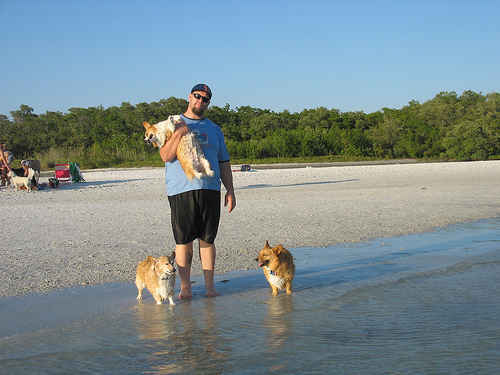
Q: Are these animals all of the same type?
A: Yes, all the animals are dogs.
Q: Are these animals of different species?
A: No, all the animals are dogs.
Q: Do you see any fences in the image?
A: No, there are no fences.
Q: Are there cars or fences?
A: No, there are no fences or cars.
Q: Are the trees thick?
A: Yes, the trees are thick.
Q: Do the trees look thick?
A: Yes, the trees are thick.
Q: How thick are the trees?
A: The trees are thick.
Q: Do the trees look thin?
A: No, the trees are thick.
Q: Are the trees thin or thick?
A: The trees are thick.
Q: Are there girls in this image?
A: No, there are no girls.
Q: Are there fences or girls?
A: No, there are no girls or fences.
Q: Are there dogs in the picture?
A: Yes, there is a dog.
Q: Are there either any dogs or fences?
A: Yes, there is a dog.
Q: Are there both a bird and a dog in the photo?
A: No, there is a dog but no birds.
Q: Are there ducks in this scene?
A: No, there are no ducks.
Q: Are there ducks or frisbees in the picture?
A: No, there are no ducks or frisbees.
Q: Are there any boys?
A: No, there are no boys.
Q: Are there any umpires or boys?
A: No, there are no boys or umpires.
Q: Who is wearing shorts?
A: The man is wearing shorts.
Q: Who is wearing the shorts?
A: The man is wearing shorts.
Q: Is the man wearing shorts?
A: Yes, the man is wearing shorts.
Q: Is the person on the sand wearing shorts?
A: Yes, the man is wearing shorts.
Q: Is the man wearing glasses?
A: No, the man is wearing shorts.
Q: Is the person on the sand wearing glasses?
A: No, the man is wearing shorts.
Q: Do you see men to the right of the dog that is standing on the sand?
A: Yes, there is a man to the right of the dog.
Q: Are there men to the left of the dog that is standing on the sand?
A: No, the man is to the right of the dog.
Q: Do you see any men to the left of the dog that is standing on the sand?
A: No, the man is to the right of the dog.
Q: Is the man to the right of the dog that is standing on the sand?
A: Yes, the man is to the right of the dog.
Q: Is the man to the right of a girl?
A: No, the man is to the right of the dog.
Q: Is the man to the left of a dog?
A: No, the man is to the right of a dog.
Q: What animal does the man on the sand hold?
A: The man holds the dog.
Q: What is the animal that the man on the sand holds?
A: The animal is a dog.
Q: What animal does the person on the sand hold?
A: The man holds the dog.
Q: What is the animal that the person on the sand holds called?
A: The animal is a dog.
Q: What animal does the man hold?
A: The man holds the dog.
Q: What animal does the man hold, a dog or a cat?
A: The man holds a dog.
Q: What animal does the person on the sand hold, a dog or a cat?
A: The man holds a dog.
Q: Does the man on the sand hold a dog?
A: Yes, the man holds a dog.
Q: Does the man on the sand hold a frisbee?
A: No, the man holds a dog.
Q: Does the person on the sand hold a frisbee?
A: No, the man holds a dog.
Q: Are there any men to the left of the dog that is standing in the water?
A: Yes, there is a man to the left of the dog.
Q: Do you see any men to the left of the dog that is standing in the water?
A: Yes, there is a man to the left of the dog.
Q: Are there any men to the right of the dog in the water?
A: No, the man is to the left of the dog.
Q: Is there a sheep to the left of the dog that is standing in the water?
A: No, there is a man to the left of the dog.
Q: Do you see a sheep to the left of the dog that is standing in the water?
A: No, there is a man to the left of the dog.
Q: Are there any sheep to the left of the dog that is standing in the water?
A: No, there is a man to the left of the dog.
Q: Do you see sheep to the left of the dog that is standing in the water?
A: No, there is a man to the left of the dog.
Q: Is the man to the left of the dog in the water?
A: Yes, the man is to the left of the dog.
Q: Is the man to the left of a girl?
A: No, the man is to the left of the dog.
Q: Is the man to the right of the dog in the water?
A: No, the man is to the left of the dog.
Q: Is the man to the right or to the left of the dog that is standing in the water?
A: The man is to the left of the dog.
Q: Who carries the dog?
A: The man carries the dog.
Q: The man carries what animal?
A: The man carries a dog.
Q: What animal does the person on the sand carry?
A: The man carries a dog.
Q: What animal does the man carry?
A: The man carries a dog.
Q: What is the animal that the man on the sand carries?
A: The animal is a dog.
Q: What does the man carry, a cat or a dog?
A: The man carries a dog.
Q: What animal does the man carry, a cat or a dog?
A: The man carries a dog.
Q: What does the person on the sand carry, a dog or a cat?
A: The man carries a dog.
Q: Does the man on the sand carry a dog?
A: Yes, the man carries a dog.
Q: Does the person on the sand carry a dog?
A: Yes, the man carries a dog.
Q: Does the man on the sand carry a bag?
A: No, the man carries a dog.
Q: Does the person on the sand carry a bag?
A: No, the man carries a dog.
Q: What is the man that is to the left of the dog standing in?
A: The man is standing in the water.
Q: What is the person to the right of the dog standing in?
A: The man is standing in the water.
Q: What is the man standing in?
A: The man is standing in the water.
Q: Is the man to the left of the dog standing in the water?
A: Yes, the man is standing in the water.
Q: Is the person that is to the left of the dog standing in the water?
A: Yes, the man is standing in the water.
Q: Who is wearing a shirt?
A: The man is wearing a shirt.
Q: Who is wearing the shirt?
A: The man is wearing a shirt.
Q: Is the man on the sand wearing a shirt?
A: Yes, the man is wearing a shirt.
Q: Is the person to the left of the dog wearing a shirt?
A: Yes, the man is wearing a shirt.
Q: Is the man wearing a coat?
A: No, the man is wearing a shirt.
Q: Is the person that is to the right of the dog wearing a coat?
A: No, the man is wearing a shirt.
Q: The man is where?
A: The man is on the sand.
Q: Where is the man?
A: The man is on the sand.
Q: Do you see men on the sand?
A: Yes, there is a man on the sand.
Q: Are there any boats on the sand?
A: No, there is a man on the sand.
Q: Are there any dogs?
A: Yes, there is a dog.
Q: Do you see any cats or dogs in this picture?
A: Yes, there is a dog.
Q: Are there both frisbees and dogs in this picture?
A: No, there is a dog but no frisbees.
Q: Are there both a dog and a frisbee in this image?
A: No, there is a dog but no frisbees.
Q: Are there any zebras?
A: No, there are no zebras.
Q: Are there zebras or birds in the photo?
A: No, there are no zebras or birds.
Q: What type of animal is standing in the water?
A: The animal is a dog.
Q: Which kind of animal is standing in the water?
A: The animal is a dog.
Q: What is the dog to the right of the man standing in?
A: The dog is standing in the water.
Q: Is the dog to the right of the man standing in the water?
A: Yes, the dog is standing in the water.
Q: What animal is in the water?
A: The dog is in the water.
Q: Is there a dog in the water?
A: Yes, there is a dog in the water.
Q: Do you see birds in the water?
A: No, there is a dog in the water.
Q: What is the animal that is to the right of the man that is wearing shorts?
A: The animal is a dog.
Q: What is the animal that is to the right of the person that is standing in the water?
A: The animal is a dog.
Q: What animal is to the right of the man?
A: The animal is a dog.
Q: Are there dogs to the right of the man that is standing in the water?
A: Yes, there is a dog to the right of the man.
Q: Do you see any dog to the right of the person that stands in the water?
A: Yes, there is a dog to the right of the man.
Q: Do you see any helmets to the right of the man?
A: No, there is a dog to the right of the man.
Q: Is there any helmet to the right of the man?
A: No, there is a dog to the right of the man.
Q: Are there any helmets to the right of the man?
A: No, there is a dog to the right of the man.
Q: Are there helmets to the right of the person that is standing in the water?
A: No, there is a dog to the right of the man.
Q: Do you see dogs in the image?
A: Yes, there is a dog.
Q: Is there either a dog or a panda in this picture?
A: Yes, there is a dog.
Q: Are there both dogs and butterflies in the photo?
A: No, there is a dog but no butterflies.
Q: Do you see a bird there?
A: No, there are no birds.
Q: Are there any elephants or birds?
A: No, there are no birds or elephants.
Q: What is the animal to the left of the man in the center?
A: The animal is a dog.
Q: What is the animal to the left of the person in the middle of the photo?
A: The animal is a dog.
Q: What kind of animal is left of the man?
A: The animal is a dog.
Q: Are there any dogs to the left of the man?
A: Yes, there is a dog to the left of the man.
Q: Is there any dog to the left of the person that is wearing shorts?
A: Yes, there is a dog to the left of the man.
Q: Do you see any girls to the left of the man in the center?
A: No, there is a dog to the left of the man.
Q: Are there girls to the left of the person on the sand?
A: No, there is a dog to the left of the man.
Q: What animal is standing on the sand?
A: The dog is standing on the sand.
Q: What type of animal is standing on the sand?
A: The animal is a dog.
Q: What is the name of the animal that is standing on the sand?
A: The animal is a dog.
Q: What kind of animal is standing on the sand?
A: The animal is a dog.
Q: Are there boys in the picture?
A: No, there are no boys.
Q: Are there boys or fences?
A: No, there are no boys or fences.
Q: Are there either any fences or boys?
A: No, there are no boys or fences.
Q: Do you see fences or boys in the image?
A: No, there are no boys or fences.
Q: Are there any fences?
A: No, there are no fences.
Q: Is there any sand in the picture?
A: Yes, there is sand.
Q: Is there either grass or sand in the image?
A: Yes, there is sand.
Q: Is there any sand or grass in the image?
A: Yes, there is sand.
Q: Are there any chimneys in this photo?
A: No, there are no chimneys.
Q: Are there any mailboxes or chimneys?
A: No, there are no chimneys or mailboxes.